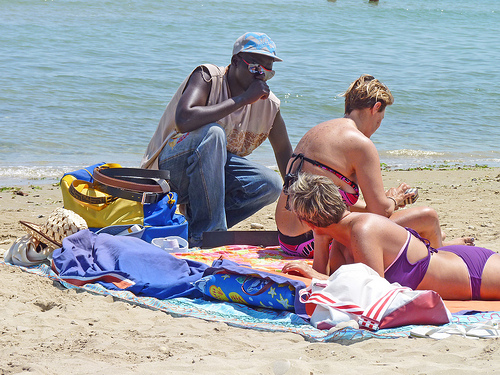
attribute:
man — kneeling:
[142, 32, 290, 260]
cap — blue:
[230, 29, 283, 61]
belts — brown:
[69, 166, 163, 210]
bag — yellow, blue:
[61, 161, 191, 241]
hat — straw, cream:
[15, 206, 86, 250]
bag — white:
[298, 263, 454, 327]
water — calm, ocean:
[2, 0, 499, 162]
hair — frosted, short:
[284, 170, 349, 227]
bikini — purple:
[384, 228, 495, 297]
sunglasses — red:
[226, 48, 277, 80]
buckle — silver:
[140, 189, 156, 208]